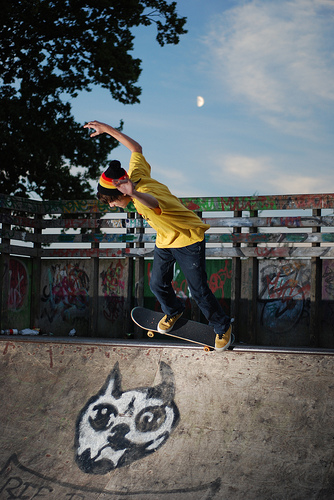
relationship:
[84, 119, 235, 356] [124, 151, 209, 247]
boy has shirt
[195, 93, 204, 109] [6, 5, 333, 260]
half moon in sky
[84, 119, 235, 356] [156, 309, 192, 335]
boy has tennis shoe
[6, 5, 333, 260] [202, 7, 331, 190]
sky has cloud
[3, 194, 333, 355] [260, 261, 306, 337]
fence has number 5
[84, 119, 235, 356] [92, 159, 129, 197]
boy has hat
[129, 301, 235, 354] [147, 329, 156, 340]
skateboard has wheel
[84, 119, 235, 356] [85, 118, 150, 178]
boy has arm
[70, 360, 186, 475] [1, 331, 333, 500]
dog on ramp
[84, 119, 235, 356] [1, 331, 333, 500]
boy on top of ramp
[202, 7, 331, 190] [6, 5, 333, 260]
cloud in sky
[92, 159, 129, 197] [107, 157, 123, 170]
hat has pom pom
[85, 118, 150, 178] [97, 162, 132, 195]
arm over head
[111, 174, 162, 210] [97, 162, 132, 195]
arm over head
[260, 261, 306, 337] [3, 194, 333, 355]
number 5 on fence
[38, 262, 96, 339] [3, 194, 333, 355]
graffiti on fence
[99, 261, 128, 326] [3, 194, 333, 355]
graffiti on fence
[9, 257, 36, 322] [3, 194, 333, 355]
graffiti on fence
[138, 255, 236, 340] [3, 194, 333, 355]
graffiti on fence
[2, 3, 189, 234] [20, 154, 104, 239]
tree has branch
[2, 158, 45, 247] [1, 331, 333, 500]
brance near ramp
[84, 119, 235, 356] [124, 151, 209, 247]
boy wears shirt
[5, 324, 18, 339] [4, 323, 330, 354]
trash strewn on platform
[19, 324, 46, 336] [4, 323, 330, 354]
trash strewn on platform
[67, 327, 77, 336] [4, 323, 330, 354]
trash strewn on platform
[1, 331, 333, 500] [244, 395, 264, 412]
ramp has mark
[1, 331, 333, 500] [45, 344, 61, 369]
ramp has mark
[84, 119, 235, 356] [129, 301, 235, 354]
boy on skateboard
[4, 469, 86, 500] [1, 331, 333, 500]
writing on ramp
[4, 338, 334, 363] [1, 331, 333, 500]
band on ramp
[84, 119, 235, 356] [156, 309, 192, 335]
boy wears tennis shoe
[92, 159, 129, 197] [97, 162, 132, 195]
hat on head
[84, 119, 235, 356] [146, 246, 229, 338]
boy wears jeans